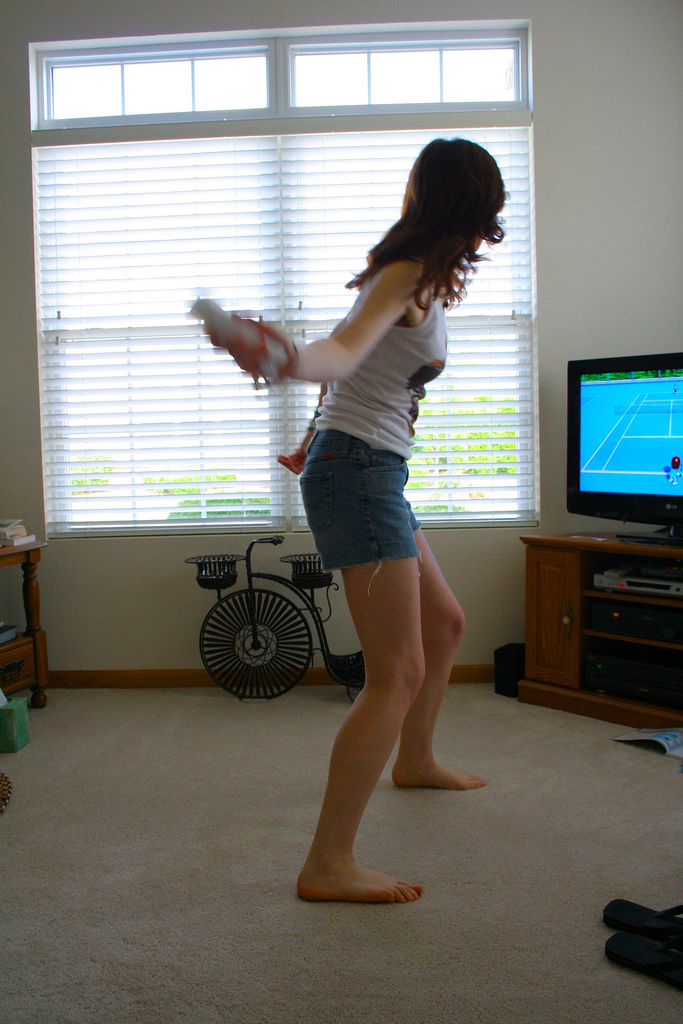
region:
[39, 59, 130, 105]
a window on a building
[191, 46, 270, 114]
a window on a building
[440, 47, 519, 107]
a window on a building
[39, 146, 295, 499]
a window on a building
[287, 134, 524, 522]
a window on a building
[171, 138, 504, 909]
a person is playing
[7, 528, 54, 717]
a normal table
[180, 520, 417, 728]
a decorative bicycle stand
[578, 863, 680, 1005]
slippers on the carpeted floor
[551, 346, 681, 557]
a black television screen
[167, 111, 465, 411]
a lady holding gaming console remote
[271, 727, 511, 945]
bare feet on a carpet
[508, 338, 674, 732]
a wooden TV stand cabinet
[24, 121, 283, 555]
window with white blind shutters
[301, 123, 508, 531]
a lady wearing a tank top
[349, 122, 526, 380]
a caucasian lady with brown hair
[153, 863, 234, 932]
a view of surface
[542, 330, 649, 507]
a view of tv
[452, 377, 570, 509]
a view of window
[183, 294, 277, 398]
a view of hand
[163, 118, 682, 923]
a woman playing Wii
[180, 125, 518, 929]
the woman is bare feet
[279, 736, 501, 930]
two feet of a woman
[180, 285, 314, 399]
hand hold a Wii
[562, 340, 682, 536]
a TV is turn on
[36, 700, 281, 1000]
the carpet is brown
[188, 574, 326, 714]
the wheel is black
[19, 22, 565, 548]
a woman on front a window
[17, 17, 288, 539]
blind over a window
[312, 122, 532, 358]
woman has black hair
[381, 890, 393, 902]
the short toe of the foot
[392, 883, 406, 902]
the short toe of the foot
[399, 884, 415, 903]
the short toe of the foot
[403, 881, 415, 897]
the short toe of the foot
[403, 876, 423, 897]
the short toe of the foot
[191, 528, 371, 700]
the black metal bike decoration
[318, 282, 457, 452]
the white tank top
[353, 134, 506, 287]
the brown hair of the head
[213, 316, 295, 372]
the hand of the girl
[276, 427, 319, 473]
the hand of the girl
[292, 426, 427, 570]
woman wearing blue jean shorts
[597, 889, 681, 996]
black flip flops on floor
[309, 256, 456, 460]
woman wearing white tank top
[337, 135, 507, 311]
woman with long brown hair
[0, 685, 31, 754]
green box of kleenex on floor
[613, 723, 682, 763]
magazine open on floor by television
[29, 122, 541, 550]
white blinds on window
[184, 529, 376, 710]
black metal decoration in front of window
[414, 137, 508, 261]
person has a head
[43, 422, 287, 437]
mini blind is white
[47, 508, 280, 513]
mini blind is white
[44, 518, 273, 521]
mini blind is white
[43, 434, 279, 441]
mini blind is white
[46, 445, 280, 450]
mini blind is white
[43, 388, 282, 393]
mini blind is white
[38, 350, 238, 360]
mini blind is white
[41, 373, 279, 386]
mini blind is white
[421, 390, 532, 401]
mini blind is white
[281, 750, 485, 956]
the feet are bare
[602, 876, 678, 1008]
flip flops on the carpet